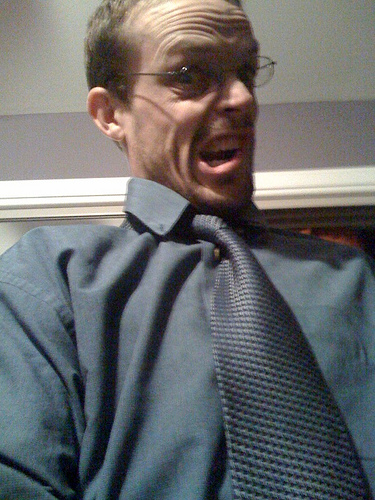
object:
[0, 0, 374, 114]
ceiling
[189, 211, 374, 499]
tie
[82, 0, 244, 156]
hair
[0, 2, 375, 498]
man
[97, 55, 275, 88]
glasses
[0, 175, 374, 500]
shirt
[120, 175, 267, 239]
collar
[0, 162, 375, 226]
trim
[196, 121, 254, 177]
mouth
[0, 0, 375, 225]
wall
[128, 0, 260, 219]
face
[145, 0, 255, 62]
wrinkles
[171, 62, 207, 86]
eye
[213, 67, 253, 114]
nose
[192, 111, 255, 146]
facial hair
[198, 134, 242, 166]
teeth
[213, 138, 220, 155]
tooth